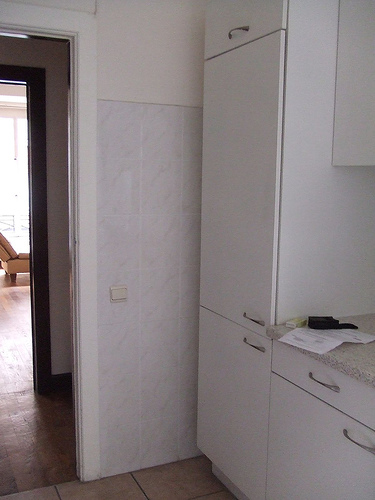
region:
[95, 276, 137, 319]
Plastic light switch.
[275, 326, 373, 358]
Paper document on a granite counter.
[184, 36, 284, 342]
Tall white cabinet with metal handle.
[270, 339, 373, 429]
Wide drawer with metal handle.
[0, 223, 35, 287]
Brown couch with wooden posts.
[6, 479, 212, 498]
Brown linoleum tiles.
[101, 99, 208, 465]
White tiled wall.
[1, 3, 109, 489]
White door jamb.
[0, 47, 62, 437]
Brown door jamb.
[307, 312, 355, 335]
Black cell phone case.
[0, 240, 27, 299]
tan leathery style chair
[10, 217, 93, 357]
chair is in another room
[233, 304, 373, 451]
thin silver cabinet handles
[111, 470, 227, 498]
large brownish ceramic tiles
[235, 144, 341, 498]
white plain cabinets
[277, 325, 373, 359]
paperwork on the counter top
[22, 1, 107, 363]
doorway to other room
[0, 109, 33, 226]
window in other room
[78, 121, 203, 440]
tile design on wall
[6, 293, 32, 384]
wooden flooring in room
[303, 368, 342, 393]
Handle on a white drawer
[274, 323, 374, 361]
Paper on top of the kitchen granite top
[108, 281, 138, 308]
Light switch for turning lights on or off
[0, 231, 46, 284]
Brown reclining couch in the background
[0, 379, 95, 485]
Hallway space between rooms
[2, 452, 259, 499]
Square tiles on the floor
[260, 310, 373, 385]
Granite top with a pattern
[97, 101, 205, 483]
White tile wall in the kitchen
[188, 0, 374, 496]
Kitchen cabinets and drawers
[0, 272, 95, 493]
Brown wood hardwood floor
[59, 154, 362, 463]
White kitchen cabinets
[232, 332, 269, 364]
The handle on a white cabinet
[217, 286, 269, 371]
Two handles on white cabinets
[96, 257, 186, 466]
A white tile wall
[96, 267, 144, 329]
A white light switch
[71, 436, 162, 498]
A beige tile floor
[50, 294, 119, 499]
A white door frame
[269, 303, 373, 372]
A paper on a counter top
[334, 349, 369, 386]
The edge of a countertop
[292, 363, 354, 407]
The handle on a white drawer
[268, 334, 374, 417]
White individual drawer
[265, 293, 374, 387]
A kitchen top with granite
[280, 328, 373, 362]
A paper on the counter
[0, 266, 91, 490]
A brown hardwood floor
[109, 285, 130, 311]
A light switch in the kitchen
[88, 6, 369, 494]
The kitchen area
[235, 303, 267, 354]
Handles for opening drawers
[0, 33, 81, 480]
Entrance to the kitchen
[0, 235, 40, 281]
Brown sofa next door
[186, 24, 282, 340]
A large white cabinet